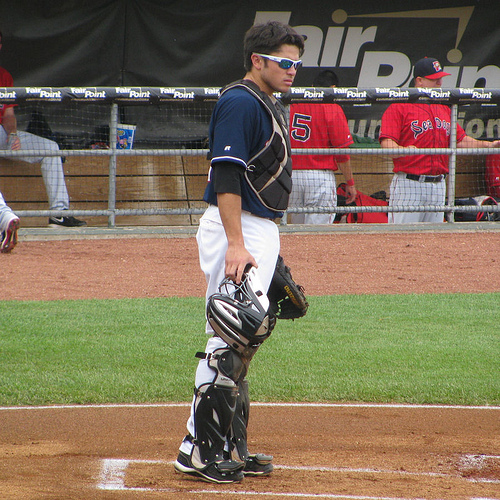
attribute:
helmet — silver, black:
[202, 267, 283, 355]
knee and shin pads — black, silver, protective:
[197, 347, 245, 483]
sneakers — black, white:
[169, 443, 254, 488]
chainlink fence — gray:
[2, 92, 498, 223]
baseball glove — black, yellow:
[269, 256, 316, 322]